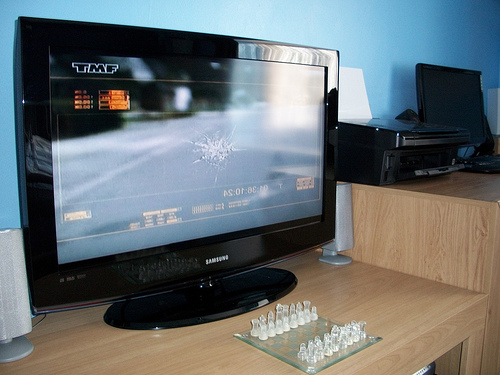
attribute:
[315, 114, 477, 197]
stereo system — black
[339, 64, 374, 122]
paper — white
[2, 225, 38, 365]
computer speaker — small, white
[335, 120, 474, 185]
printer — black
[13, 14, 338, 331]
monitor — big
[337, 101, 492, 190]
printer — black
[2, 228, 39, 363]
speakers — left hand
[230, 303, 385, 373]
chess — glass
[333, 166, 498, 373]
desk — wooden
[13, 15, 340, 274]
tv — black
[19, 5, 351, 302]
monitor — large, black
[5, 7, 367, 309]
tv — flat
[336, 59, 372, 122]
paper — white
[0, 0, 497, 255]
wall — blue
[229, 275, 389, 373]
chess — clear, frosted, glass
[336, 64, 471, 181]
computer printer — black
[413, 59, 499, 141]
monitor — small, black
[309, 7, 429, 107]
blue walls — light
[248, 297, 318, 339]
pieces — chess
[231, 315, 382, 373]
board — glass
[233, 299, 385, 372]
chess set — ready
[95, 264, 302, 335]
tv stand — black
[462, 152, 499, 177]
computer keyboard — black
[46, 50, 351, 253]
tv — right hand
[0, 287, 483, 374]
table — wooden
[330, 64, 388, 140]
paper — white